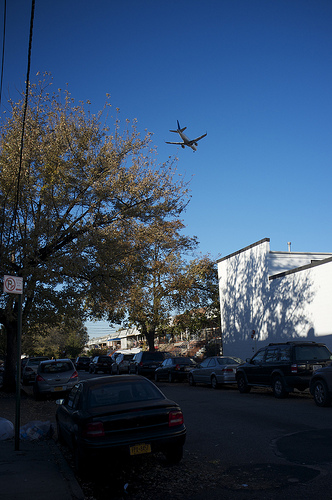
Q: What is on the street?
A: A car.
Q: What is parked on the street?
A: Cars.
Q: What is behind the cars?
A: A tall white building.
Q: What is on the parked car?
A: Yellow license plate.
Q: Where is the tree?
A: On the far side of road.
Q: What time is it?
A: Afternoon.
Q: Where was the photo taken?
A: Outside somewhere.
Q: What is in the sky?
A: Plane.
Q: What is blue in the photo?
A: The sky.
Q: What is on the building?
A: Shadow.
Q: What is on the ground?
A: Cars.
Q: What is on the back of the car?
A: License plate.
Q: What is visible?
A: A car.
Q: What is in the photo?
A: A tree.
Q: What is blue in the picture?
A: Sky.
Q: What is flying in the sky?
A: A plane.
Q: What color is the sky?
A: Blue.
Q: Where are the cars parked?
A: Street.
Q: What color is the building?
A: White.